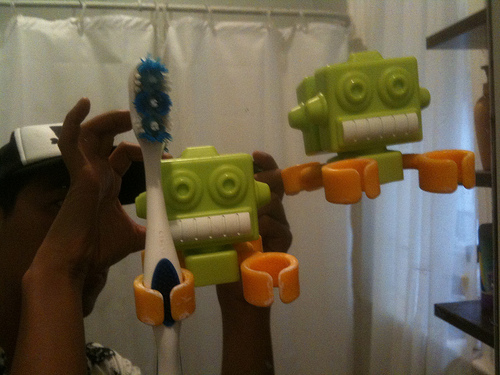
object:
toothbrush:
[127, 59, 182, 375]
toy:
[131, 146, 298, 327]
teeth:
[341, 113, 418, 144]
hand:
[321, 157, 380, 204]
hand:
[417, 149, 477, 192]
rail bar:
[0, 0, 348, 20]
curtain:
[2, 14, 350, 375]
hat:
[0, 123, 147, 206]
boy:
[0, 98, 293, 375]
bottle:
[473, 85, 488, 170]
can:
[478, 221, 495, 296]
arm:
[215, 286, 274, 375]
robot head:
[135, 144, 268, 250]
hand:
[240, 252, 300, 307]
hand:
[11, 97, 172, 375]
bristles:
[132, 55, 176, 145]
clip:
[132, 268, 195, 325]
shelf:
[425, 0, 500, 372]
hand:
[214, 150, 291, 375]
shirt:
[83, 339, 139, 375]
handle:
[143, 208, 185, 375]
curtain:
[348, 0, 496, 373]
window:
[376, 47, 478, 359]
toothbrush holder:
[279, 49, 474, 204]